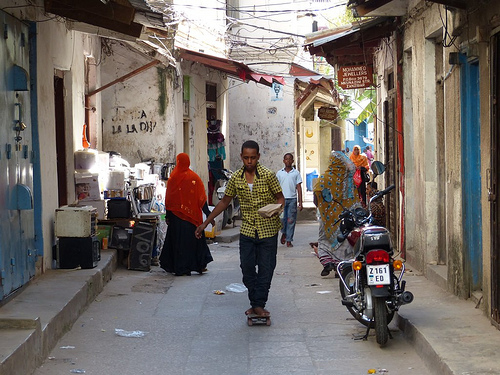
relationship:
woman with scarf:
[158, 151, 214, 280] [168, 148, 208, 232]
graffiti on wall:
[112, 110, 160, 142] [103, 43, 182, 199]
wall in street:
[103, 43, 182, 199] [57, 207, 440, 366]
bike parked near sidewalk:
[330, 184, 411, 344] [390, 262, 499, 371]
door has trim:
[460, 50, 483, 304] [457, 54, 484, 295]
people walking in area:
[160, 132, 376, 335] [8, 0, 498, 364]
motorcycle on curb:
[319, 173, 416, 353] [395, 309, 452, 373]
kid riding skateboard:
[193, 138, 291, 307] [244, 308, 270, 327]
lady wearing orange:
[156, 149, 220, 279] [163, 150, 208, 229]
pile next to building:
[57, 141, 170, 281] [0, 1, 186, 306]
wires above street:
[146, 0, 357, 65] [57, 207, 440, 366]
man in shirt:
[275, 149, 305, 247] [277, 169, 302, 205]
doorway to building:
[456, 52, 487, 293] [305, 0, 499, 331]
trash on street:
[109, 270, 340, 344] [57, 207, 440, 366]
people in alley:
[160, 132, 376, 335] [29, 189, 435, 367]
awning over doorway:
[179, 45, 290, 86] [207, 79, 221, 200]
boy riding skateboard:
[201, 143, 294, 316] [244, 308, 270, 327]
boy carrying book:
[201, 143, 294, 316] [258, 201, 284, 216]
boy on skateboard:
[201, 143, 294, 316] [244, 308, 270, 327]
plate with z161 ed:
[365, 265, 392, 290] [368, 265, 389, 280]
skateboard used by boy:
[244, 308, 270, 327] [201, 143, 294, 316]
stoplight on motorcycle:
[364, 249, 389, 268] [319, 173, 416, 353]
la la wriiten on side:
[110, 115, 139, 137] [96, 50, 184, 210]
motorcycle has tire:
[319, 173, 416, 353] [370, 293, 397, 352]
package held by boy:
[258, 201, 284, 216] [201, 143, 294, 316]